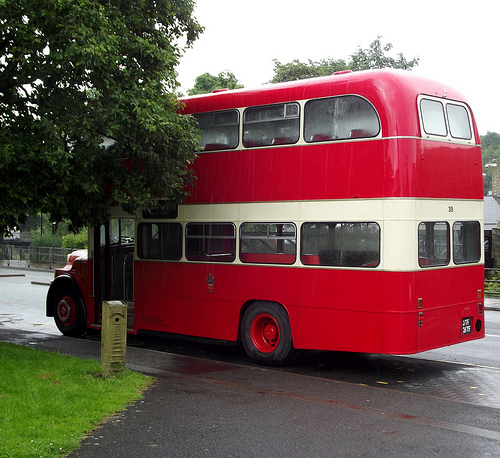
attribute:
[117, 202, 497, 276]
band — white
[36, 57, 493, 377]
bus — red, white, double decker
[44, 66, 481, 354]
bus — parked, red, white, double decker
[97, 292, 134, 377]
post — wooden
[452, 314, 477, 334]
license plate — black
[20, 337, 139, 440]
grass — green, wet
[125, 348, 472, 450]
pavement — slightly wet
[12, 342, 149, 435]
patch — bright green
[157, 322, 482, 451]
sidewalk — dark grey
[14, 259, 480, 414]
roadway — dark grey, asphalt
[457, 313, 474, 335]
license plate — black, white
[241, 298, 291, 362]
tire — black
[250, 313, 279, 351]
hubcap — red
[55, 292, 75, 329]
hubcap — red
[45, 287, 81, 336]
tire — black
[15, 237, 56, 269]
fencing — chain link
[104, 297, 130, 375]
pole — metal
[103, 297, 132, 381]
pole — metal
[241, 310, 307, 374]
wheel — back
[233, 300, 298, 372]
wheel — back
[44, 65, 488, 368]
tour bus — red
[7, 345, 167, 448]
area — grassy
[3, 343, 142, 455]
area — grassy